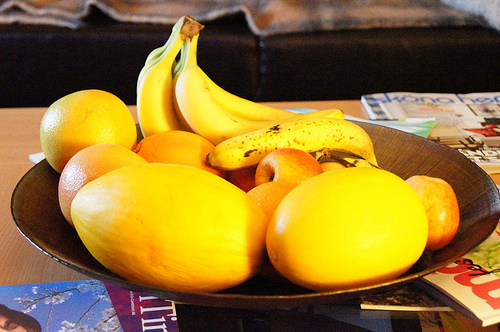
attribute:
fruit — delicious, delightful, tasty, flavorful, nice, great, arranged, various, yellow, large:
[38, 14, 459, 291]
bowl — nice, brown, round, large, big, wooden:
[11, 118, 498, 312]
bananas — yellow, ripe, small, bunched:
[134, 14, 379, 171]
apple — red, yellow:
[252, 146, 324, 187]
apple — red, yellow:
[404, 173, 460, 251]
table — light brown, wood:
[1, 98, 498, 331]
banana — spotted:
[205, 112, 378, 168]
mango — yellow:
[266, 164, 429, 291]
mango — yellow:
[64, 161, 267, 294]